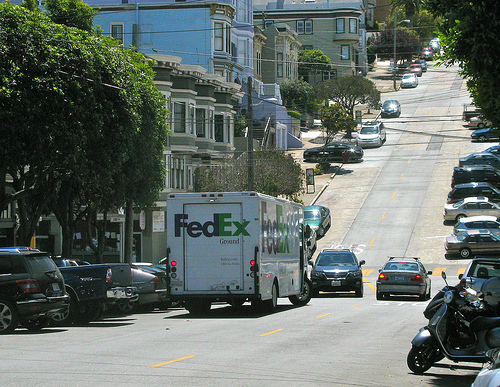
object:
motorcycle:
[402, 272, 499, 376]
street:
[33, 70, 485, 387]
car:
[373, 256, 433, 301]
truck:
[163, 190, 312, 314]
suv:
[306, 247, 367, 299]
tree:
[1, 3, 58, 246]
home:
[143, 56, 239, 199]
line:
[258, 325, 283, 339]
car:
[443, 197, 500, 224]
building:
[255, 8, 361, 78]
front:
[404, 328, 442, 374]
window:
[172, 101, 185, 131]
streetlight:
[392, 15, 413, 74]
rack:
[388, 255, 418, 260]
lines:
[126, 32, 454, 77]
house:
[101, 3, 234, 80]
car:
[354, 120, 387, 150]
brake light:
[377, 273, 386, 281]